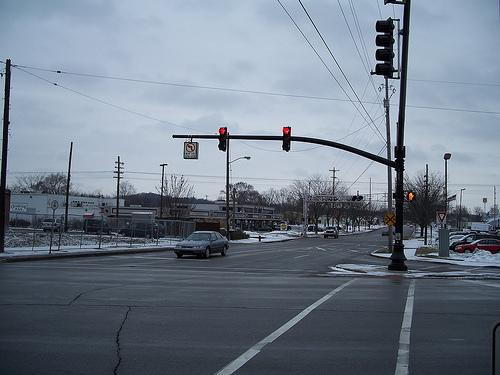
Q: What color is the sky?
A: Gray.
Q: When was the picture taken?
A: In the daytime.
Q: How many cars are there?
A: 2.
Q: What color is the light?
A: Red.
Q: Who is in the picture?
A: No one.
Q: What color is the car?
A: Blue.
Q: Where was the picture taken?
A: At a street corner.